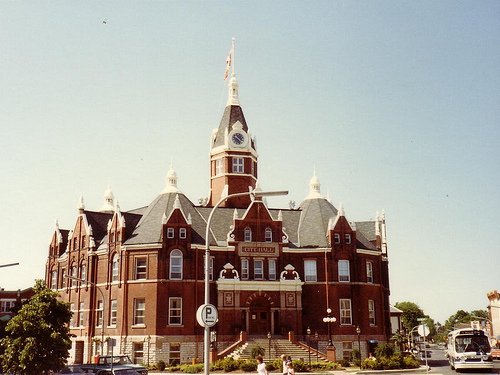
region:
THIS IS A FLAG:
[220, 35, 235, 95]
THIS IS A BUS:
[443, 325, 495, 372]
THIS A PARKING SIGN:
[193, 302, 220, 330]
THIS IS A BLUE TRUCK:
[58, 353, 149, 373]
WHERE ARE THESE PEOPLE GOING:
[252, 354, 297, 374]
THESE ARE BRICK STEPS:
[209, 328, 338, 369]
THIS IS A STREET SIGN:
[415, 313, 430, 372]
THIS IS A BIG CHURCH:
[0, 34, 392, 373]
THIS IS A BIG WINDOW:
[167, 245, 183, 283]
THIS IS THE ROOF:
[45, 161, 387, 248]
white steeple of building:
[200, 25, 256, 110]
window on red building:
[333, 285, 363, 330]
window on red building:
[330, 255, 358, 293]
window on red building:
[130, 258, 154, 292]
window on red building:
[130, 288, 158, 336]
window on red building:
[159, 289, 189, 339]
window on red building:
[169, 248, 193, 285]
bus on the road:
[445, 313, 492, 367]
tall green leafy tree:
[0, 275, 85, 370]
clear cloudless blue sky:
[42, 31, 142, 156]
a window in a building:
[163, 292, 188, 330]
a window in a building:
[165, 245, 187, 282]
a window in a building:
[131, 250, 151, 283]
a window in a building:
[130, 298, 150, 333]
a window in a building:
[167, 340, 183, 366]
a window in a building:
[107, 299, 120, 326]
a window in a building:
[109, 250, 122, 280]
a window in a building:
[165, 223, 177, 242]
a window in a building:
[336, 256, 353, 286]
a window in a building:
[302, 257, 321, 286]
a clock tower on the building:
[209, 37, 261, 206]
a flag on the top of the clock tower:
[219, 34, 238, 79]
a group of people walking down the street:
[252, 351, 295, 373]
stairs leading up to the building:
[228, 328, 333, 365]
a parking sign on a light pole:
[196, 303, 218, 326]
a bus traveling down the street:
[443, 327, 495, 373]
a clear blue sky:
[0, 1, 498, 320]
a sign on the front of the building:
[239, 240, 278, 257]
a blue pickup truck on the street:
[64, 351, 149, 373]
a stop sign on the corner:
[416, 323, 433, 370]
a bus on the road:
[439, 323, 492, 355]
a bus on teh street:
[440, 327, 489, 362]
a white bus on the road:
[439, 308, 491, 360]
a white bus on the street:
[414, 298, 491, 374]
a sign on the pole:
[179, 276, 236, 343]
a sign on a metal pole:
[185, 286, 243, 357]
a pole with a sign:
[162, 287, 244, 372]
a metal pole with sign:
[185, 283, 244, 367]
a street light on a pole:
[172, 161, 312, 328]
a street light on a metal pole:
[154, 171, 325, 364]